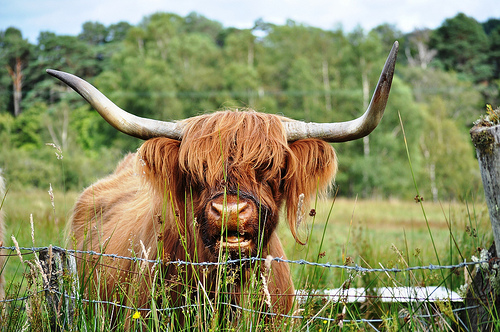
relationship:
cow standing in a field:
[41, 41, 399, 332] [356, 152, 468, 285]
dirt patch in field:
[363, 210, 458, 235] [7, 168, 498, 330]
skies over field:
[216, 0, 380, 27] [340, 210, 442, 249]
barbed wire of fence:
[0, 242, 498, 271] [0, 230, 498, 330]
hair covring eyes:
[135, 108, 342, 246] [178, 162, 279, 186]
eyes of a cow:
[178, 162, 279, 186] [17, 38, 407, 324]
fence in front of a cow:
[4, 240, 494, 330] [17, 38, 407, 324]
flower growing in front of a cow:
[119, 301, 146, 321] [37, 37, 447, 322]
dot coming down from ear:
[309, 208, 316, 217] [285, 135, 332, 229]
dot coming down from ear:
[309, 208, 316, 217] [289, 137, 334, 247]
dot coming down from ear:
[309, 208, 316, 217] [146, 129, 191, 261]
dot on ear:
[305, 203, 318, 223] [280, 139, 337, 191]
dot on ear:
[370, 62, 395, 97] [262, 125, 356, 237]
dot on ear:
[309, 208, 316, 217] [287, 130, 333, 245]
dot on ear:
[309, 208, 316, 217] [284, 138, 334, 195]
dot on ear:
[309, 208, 316, 217] [281, 135, 341, 250]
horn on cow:
[283, 42, 416, 149] [137, 101, 342, 263]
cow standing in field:
[40, 55, 389, 255] [9, 107, 499, 327]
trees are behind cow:
[2, 24, 496, 184] [41, 41, 399, 332]